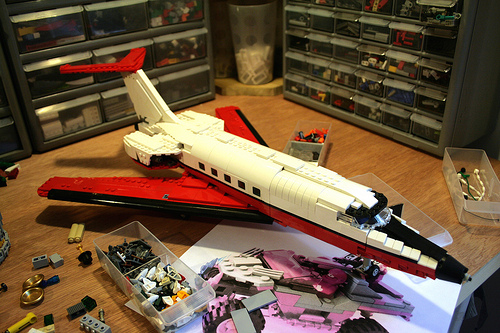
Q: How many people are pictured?
A: 0.